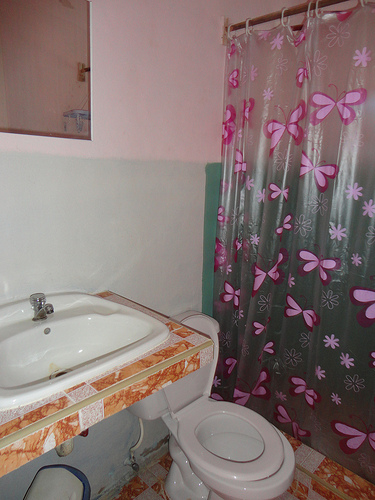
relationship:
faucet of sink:
[28, 290, 55, 321] [1, 290, 172, 412]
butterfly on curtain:
[210, 33, 375, 452] [210, 27, 372, 484]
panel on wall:
[2, 3, 92, 138] [117, 20, 226, 247]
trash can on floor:
[23, 463, 90, 498] [101, 395, 373, 497]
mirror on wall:
[1, 2, 91, 140] [2, 2, 213, 294]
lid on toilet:
[158, 311, 219, 420] [149, 331, 298, 498]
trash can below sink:
[23, 463, 90, 498] [1, 290, 172, 412]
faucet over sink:
[28, 290, 55, 321] [15, 280, 171, 405]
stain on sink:
[47, 362, 61, 373] [9, 314, 194, 398]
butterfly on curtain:
[266, 181, 288, 200] [210, 27, 372, 484]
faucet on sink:
[23, 290, 62, 315] [1, 290, 172, 412]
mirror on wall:
[1, 2, 91, 140] [0, 26, 297, 416]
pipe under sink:
[54, 436, 76, 459] [0, 290, 213, 475]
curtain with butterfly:
[209, 4, 375, 484] [305, 80, 367, 125]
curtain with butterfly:
[209, 4, 375, 484] [262, 100, 307, 156]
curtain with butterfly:
[209, 4, 375, 484] [297, 146, 339, 192]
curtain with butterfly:
[209, 4, 375, 484] [210, 33, 375, 452]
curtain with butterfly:
[209, 4, 375, 484] [284, 292, 319, 328]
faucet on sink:
[28, 290, 55, 321] [2, 308, 162, 406]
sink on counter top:
[16, 283, 162, 415] [0, 301, 210, 439]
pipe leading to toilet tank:
[127, 418, 143, 461] [127, 308, 219, 420]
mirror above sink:
[1, 2, 91, 140] [4, 282, 214, 467]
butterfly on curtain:
[210, 33, 375, 452] [206, 4, 361, 468]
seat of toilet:
[174, 396, 287, 484] [127, 309, 297, 499]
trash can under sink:
[23, 463, 90, 498] [0, 257, 233, 485]